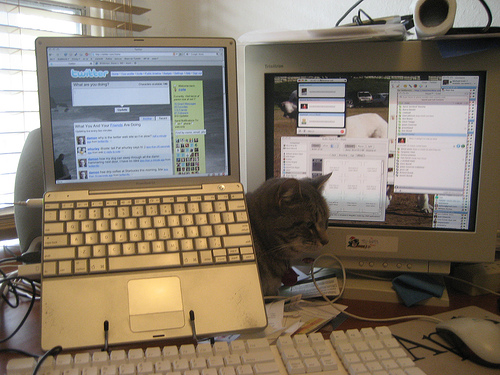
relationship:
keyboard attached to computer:
[30, 323, 399, 369] [225, 33, 451, 270]